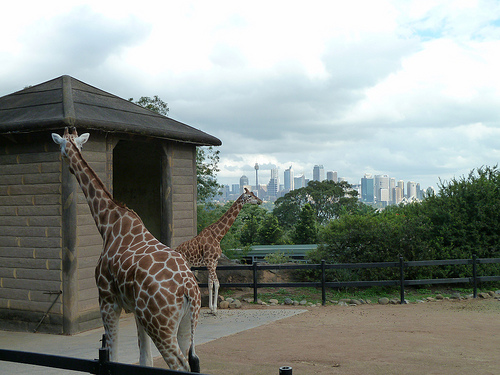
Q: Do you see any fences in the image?
A: Yes, there is a fence.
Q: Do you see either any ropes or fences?
A: Yes, there is a fence.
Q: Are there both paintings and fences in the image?
A: No, there is a fence but no paintings.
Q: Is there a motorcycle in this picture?
A: No, there are no motorcycles.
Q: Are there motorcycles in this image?
A: No, there are no motorcycles.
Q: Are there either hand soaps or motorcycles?
A: No, there are no motorcycles or hand soaps.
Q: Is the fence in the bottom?
A: Yes, the fence is in the bottom of the image.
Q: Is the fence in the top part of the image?
A: No, the fence is in the bottom of the image.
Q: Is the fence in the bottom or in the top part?
A: The fence is in the bottom of the image.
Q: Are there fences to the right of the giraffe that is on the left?
A: Yes, there is a fence to the right of the giraffe.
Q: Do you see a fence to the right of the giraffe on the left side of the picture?
A: Yes, there is a fence to the right of the giraffe.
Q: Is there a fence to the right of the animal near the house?
A: Yes, there is a fence to the right of the giraffe.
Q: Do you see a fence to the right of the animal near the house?
A: Yes, there is a fence to the right of the giraffe.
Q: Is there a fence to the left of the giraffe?
A: No, the fence is to the right of the giraffe.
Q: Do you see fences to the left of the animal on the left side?
A: No, the fence is to the right of the giraffe.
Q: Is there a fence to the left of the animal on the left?
A: No, the fence is to the right of the giraffe.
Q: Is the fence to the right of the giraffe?
A: Yes, the fence is to the right of the giraffe.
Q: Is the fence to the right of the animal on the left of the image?
A: Yes, the fence is to the right of the giraffe.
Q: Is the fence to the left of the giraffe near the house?
A: No, the fence is to the right of the giraffe.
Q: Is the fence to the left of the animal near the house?
A: No, the fence is to the right of the giraffe.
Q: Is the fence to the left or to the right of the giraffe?
A: The fence is to the right of the giraffe.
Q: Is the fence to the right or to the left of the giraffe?
A: The fence is to the right of the giraffe.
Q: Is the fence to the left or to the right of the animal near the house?
A: The fence is to the right of the giraffe.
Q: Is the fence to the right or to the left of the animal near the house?
A: The fence is to the right of the giraffe.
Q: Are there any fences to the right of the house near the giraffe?
A: Yes, there is a fence to the right of the house.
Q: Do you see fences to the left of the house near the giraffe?
A: No, the fence is to the right of the house.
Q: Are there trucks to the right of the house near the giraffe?
A: No, there is a fence to the right of the house.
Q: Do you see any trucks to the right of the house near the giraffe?
A: No, there is a fence to the right of the house.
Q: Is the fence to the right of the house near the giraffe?
A: Yes, the fence is to the right of the house.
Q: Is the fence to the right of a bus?
A: No, the fence is to the right of the house.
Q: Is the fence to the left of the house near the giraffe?
A: No, the fence is to the right of the house.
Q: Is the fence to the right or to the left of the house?
A: The fence is to the right of the house.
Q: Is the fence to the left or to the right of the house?
A: The fence is to the right of the house.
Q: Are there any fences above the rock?
A: Yes, there is a fence above the rock.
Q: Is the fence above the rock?
A: Yes, the fence is above the rock.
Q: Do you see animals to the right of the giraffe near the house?
A: Yes, there is an animal to the right of the giraffe.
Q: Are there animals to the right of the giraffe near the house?
A: Yes, there is an animal to the right of the giraffe.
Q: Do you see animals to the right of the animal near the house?
A: Yes, there is an animal to the right of the giraffe.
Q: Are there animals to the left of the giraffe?
A: No, the animal is to the right of the giraffe.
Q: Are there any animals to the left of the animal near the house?
A: No, the animal is to the right of the giraffe.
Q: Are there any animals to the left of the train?
A: Yes, there is an animal to the left of the train.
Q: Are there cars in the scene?
A: No, there are no cars.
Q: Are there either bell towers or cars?
A: No, there are no cars or bell towers.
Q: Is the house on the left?
A: Yes, the house is on the left of the image.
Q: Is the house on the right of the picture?
A: No, the house is on the left of the image.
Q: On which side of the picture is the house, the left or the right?
A: The house is on the left of the image.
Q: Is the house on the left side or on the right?
A: The house is on the left of the image.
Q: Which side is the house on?
A: The house is on the left of the image.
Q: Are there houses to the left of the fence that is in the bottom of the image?
A: Yes, there is a house to the left of the fence.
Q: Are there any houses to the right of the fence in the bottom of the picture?
A: No, the house is to the left of the fence.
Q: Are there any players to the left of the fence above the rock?
A: No, there is a house to the left of the fence.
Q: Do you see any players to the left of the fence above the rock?
A: No, there is a house to the left of the fence.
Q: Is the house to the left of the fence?
A: Yes, the house is to the left of the fence.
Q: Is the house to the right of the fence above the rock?
A: No, the house is to the left of the fence.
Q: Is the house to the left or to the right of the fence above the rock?
A: The house is to the left of the fence.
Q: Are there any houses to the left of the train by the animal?
A: Yes, there is a house to the left of the train.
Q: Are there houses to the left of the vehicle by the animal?
A: Yes, there is a house to the left of the train.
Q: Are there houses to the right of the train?
A: No, the house is to the left of the train.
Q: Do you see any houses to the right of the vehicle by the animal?
A: No, the house is to the left of the train.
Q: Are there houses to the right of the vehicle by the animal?
A: No, the house is to the left of the train.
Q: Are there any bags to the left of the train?
A: No, there is a house to the left of the train.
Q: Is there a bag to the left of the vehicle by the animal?
A: No, there is a house to the left of the train.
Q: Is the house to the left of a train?
A: Yes, the house is to the left of a train.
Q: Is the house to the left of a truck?
A: No, the house is to the left of a train.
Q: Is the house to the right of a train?
A: No, the house is to the left of a train.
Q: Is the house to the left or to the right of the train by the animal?
A: The house is to the left of the train.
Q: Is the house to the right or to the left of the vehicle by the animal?
A: The house is to the left of the train.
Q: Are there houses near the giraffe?
A: Yes, there is a house near the giraffe.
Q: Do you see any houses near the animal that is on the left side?
A: Yes, there is a house near the giraffe.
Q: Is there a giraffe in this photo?
A: Yes, there is a giraffe.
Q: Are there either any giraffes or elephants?
A: Yes, there is a giraffe.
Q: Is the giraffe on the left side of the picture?
A: Yes, the giraffe is on the left of the image.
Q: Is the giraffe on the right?
A: No, the giraffe is on the left of the image.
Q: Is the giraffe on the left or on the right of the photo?
A: The giraffe is on the left of the image.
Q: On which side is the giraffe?
A: The giraffe is on the left of the image.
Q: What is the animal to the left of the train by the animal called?
A: The animal is a giraffe.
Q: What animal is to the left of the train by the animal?
A: The animal is a giraffe.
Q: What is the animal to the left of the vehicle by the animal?
A: The animal is a giraffe.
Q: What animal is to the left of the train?
A: The animal is a giraffe.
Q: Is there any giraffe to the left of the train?
A: Yes, there is a giraffe to the left of the train.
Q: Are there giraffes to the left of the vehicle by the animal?
A: Yes, there is a giraffe to the left of the train.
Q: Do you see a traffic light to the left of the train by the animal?
A: No, there is a giraffe to the left of the train.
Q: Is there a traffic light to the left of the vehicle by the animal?
A: No, there is a giraffe to the left of the train.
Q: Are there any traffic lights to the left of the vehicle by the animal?
A: No, there is a giraffe to the left of the train.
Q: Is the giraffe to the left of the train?
A: Yes, the giraffe is to the left of the train.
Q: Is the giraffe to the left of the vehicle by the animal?
A: Yes, the giraffe is to the left of the train.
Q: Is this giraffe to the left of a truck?
A: No, the giraffe is to the left of the train.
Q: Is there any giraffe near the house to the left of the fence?
A: Yes, there is a giraffe near the house.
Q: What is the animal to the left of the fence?
A: The animal is a giraffe.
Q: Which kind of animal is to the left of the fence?
A: The animal is a giraffe.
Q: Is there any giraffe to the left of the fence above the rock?
A: Yes, there is a giraffe to the left of the fence.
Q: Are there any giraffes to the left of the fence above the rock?
A: Yes, there is a giraffe to the left of the fence.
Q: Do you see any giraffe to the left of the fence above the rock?
A: Yes, there is a giraffe to the left of the fence.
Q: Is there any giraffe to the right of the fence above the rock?
A: No, the giraffe is to the left of the fence.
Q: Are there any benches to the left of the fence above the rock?
A: No, there is a giraffe to the left of the fence.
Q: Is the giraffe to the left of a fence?
A: Yes, the giraffe is to the left of a fence.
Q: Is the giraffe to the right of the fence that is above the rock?
A: No, the giraffe is to the left of the fence.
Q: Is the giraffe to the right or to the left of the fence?
A: The giraffe is to the left of the fence.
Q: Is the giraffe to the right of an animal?
A: No, the giraffe is to the left of an animal.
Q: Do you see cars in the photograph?
A: No, there are no cars.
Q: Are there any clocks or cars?
A: No, there are no cars or clocks.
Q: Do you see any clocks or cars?
A: No, there are no cars or clocks.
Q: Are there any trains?
A: Yes, there is a train.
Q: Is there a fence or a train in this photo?
A: Yes, there is a train.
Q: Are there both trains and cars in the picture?
A: No, there is a train but no cars.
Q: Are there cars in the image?
A: No, there are no cars.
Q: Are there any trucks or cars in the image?
A: No, there are no cars or trucks.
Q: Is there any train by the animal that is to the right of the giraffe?
A: Yes, there is a train by the animal.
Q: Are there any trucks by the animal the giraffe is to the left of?
A: No, there is a train by the animal.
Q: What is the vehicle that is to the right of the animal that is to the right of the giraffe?
A: The vehicle is a train.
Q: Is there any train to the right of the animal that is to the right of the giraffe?
A: Yes, there is a train to the right of the animal.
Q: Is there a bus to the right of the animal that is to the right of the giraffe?
A: No, there is a train to the right of the animal.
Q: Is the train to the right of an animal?
A: Yes, the train is to the right of an animal.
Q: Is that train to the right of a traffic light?
A: No, the train is to the right of an animal.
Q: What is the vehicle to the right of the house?
A: The vehicle is a train.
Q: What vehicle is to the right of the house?
A: The vehicle is a train.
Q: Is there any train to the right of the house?
A: Yes, there is a train to the right of the house.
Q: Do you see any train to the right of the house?
A: Yes, there is a train to the right of the house.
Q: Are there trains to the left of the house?
A: No, the train is to the right of the house.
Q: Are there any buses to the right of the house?
A: No, there is a train to the right of the house.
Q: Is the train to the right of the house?
A: Yes, the train is to the right of the house.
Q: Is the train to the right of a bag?
A: No, the train is to the right of the house.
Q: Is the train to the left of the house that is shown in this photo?
A: No, the train is to the right of the house.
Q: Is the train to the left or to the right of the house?
A: The train is to the right of the house.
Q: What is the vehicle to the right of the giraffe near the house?
A: The vehicle is a train.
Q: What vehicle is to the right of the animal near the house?
A: The vehicle is a train.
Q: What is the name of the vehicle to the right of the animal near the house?
A: The vehicle is a train.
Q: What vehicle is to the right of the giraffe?
A: The vehicle is a train.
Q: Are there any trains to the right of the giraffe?
A: Yes, there is a train to the right of the giraffe.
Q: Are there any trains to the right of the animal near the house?
A: Yes, there is a train to the right of the giraffe.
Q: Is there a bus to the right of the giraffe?
A: No, there is a train to the right of the giraffe.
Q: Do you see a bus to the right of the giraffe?
A: No, there is a train to the right of the giraffe.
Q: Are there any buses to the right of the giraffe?
A: No, there is a train to the right of the giraffe.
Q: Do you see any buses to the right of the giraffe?
A: No, there is a train to the right of the giraffe.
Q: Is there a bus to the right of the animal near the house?
A: No, there is a train to the right of the giraffe.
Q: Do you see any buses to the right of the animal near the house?
A: No, there is a train to the right of the giraffe.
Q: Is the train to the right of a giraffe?
A: Yes, the train is to the right of a giraffe.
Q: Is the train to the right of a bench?
A: No, the train is to the right of a giraffe.